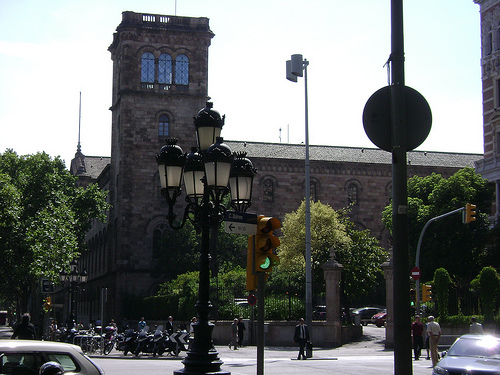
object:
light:
[252, 254, 275, 271]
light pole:
[285, 52, 321, 359]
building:
[33, 0, 499, 344]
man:
[290, 310, 314, 368]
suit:
[291, 324, 311, 357]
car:
[1, 330, 110, 375]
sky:
[1, 1, 481, 162]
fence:
[133, 275, 328, 320]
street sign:
[216, 204, 264, 239]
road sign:
[408, 262, 423, 283]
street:
[5, 331, 472, 374]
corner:
[283, 244, 391, 364]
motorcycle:
[147, 322, 187, 361]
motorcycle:
[131, 322, 166, 359]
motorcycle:
[118, 327, 144, 361]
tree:
[1, 131, 115, 345]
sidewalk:
[0, 321, 441, 375]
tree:
[0, 142, 29, 332]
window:
[137, 41, 157, 89]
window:
[153, 43, 173, 91]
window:
[172, 51, 193, 90]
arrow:
[227, 221, 238, 232]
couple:
[227, 313, 253, 353]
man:
[416, 312, 448, 371]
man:
[410, 312, 430, 363]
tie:
[300, 324, 306, 343]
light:
[282, 39, 316, 87]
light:
[195, 135, 239, 214]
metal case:
[194, 134, 240, 223]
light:
[219, 146, 261, 213]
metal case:
[224, 147, 261, 217]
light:
[173, 143, 214, 211]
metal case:
[174, 145, 209, 205]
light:
[153, 135, 188, 194]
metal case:
[148, 136, 192, 217]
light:
[189, 96, 227, 156]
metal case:
[189, 95, 233, 157]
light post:
[173, 213, 227, 373]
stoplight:
[419, 282, 434, 305]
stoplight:
[463, 202, 480, 228]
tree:
[268, 188, 351, 323]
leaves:
[296, 231, 304, 241]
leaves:
[447, 182, 458, 193]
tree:
[417, 146, 494, 317]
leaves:
[45, 222, 57, 231]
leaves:
[1, 177, 13, 188]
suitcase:
[304, 340, 316, 362]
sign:
[359, 83, 438, 156]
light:
[256, 234, 276, 253]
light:
[260, 215, 277, 236]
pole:
[410, 202, 469, 327]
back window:
[36, 343, 87, 374]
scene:
[3, 5, 496, 372]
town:
[3, 1, 495, 375]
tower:
[89, 0, 224, 324]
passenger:
[0, 347, 30, 375]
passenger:
[19, 349, 45, 375]